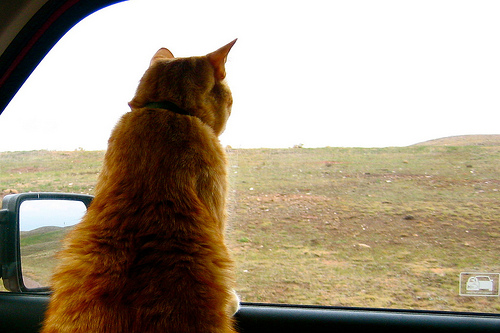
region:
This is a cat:
[125, 101, 227, 261]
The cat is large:
[125, 196, 220, 297]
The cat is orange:
[106, 176, 281, 312]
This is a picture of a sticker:
[419, 263, 497, 305]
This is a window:
[282, 187, 360, 322]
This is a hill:
[417, 108, 478, 128]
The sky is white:
[366, 37, 483, 331]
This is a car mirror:
[29, 237, 46, 244]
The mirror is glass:
[1, 206, 65, 282]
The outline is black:
[0, 183, 38, 208]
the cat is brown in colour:
[64, 36, 267, 326]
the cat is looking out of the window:
[28, 27, 258, 324]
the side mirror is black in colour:
[0, 199, 35, 290]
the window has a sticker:
[447, 268, 499, 296]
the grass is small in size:
[258, 172, 389, 287]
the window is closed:
[269, 73, 430, 277]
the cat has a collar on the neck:
[77, 66, 215, 128]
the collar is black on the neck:
[131, 85, 196, 117]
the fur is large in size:
[99, 165, 181, 290]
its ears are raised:
[148, 38, 245, 76]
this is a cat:
[70, 58, 248, 330]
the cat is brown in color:
[114, 155, 189, 273]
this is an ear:
[207, 35, 247, 67]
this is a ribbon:
[148, 95, 173, 112]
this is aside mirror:
[0, 196, 61, 255]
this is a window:
[296, 44, 437, 222]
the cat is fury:
[139, 172, 196, 278]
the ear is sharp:
[205, 35, 240, 66]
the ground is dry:
[319, 145, 419, 228]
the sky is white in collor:
[289, 29, 414, 116]